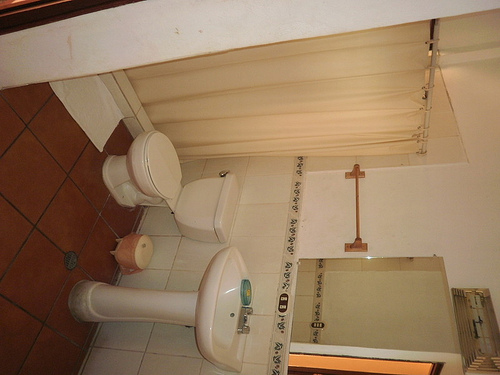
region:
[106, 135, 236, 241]
white toilet in bathroom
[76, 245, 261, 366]
white sing in bathroom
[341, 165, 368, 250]
wooden towel rack in bathroom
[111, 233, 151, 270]
basket sitting by toilet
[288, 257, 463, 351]
grey area of wall in room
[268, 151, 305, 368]
row of wall paper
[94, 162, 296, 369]
tiled part of wall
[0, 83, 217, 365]
red tiled floor of room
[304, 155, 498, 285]
white wall by shower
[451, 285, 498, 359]
light above sink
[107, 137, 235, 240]
white toilet by shower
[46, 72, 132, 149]
white mat by shower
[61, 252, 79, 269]
drain on floor by sink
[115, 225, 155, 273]
basket sitting on floor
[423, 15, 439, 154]
white curtain rod in room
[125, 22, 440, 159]
white shower curtain is hanging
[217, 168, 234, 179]
silver handle of toilet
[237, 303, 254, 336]
silver handle of sink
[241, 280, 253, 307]
blue plastic item on sink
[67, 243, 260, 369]
white sink in bathroom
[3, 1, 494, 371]
A bathroom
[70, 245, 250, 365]
A white bathroom sink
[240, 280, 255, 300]
A blue soapdish.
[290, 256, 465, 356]
a bathroom mirror.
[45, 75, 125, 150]
A white bath mat.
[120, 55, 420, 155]
A cream colored shower curtain.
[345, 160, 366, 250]
A brown wooden towel rack.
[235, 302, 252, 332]
Silver sink faucet.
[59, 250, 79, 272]
A drain on the floor.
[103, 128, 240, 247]
A white toilet.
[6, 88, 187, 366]
red tiled floor in bathroom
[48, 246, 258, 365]
white porcelain sink in bathroom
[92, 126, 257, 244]
white porcelain toilet in bathroom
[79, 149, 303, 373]
white tiled wall behind toilet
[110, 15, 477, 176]
white plastic shower curtain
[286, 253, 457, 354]
rectangular mirror above sink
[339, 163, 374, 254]
wooden towel rack above toilet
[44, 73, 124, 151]
white towel outside shower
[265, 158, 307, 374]
floral tile trim on wall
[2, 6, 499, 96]
white plaster wall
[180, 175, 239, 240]
the tank is against the wall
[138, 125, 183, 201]
the toilet seat is down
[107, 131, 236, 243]
the toilet is white in color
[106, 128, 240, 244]
the toilet is made of ceramic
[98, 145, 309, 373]
the wall is tiled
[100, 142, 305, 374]
the tiles are white in color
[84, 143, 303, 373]
the tiles are ceramic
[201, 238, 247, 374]
the sink is against the wall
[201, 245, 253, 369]
the sink is white in color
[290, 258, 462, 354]
the mirror is above the sink